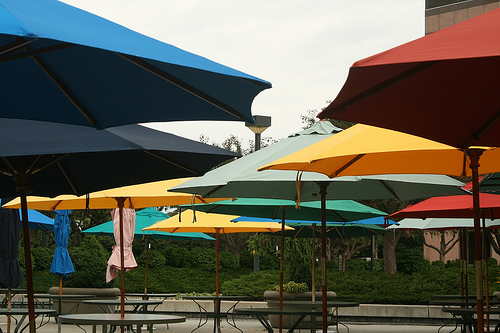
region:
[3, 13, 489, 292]
a whole lot of umbrellas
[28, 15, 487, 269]
they are all different colors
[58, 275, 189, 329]
they provide shade for the tables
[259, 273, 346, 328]
the concrete pots have bushes in them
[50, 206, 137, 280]
these umbrellas are not open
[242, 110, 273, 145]
an overhead light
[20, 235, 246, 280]
many neatly trimmed bushes line the area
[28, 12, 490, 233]
the umbrellas are blue, red, yellow, green & white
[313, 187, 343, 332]
the posts appear to be wooden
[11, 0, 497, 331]
this photo was taken on a cloudy day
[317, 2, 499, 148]
an open red umbrella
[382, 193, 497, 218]
an open red umbrella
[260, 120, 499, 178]
an open yellow umbrella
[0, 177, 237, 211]
an open yellow umbrella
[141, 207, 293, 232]
an open yellow umbrella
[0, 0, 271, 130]
an open blue umbrella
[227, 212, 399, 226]
an open blue umbrella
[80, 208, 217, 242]
an open blue umbrella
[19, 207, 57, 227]
an open blue umbrella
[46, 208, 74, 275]
an closed blue umbrella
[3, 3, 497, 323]
large patio umbrellas above tables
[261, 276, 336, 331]
cement planter on patio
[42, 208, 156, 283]
closed patio umbrellas on tables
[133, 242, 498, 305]
bushes by patio wall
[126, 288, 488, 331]
cement wall around patio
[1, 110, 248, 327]
large umbrella with wooden ribs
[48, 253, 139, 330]
cement planter with bush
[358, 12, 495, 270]
stone building by tree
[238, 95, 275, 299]
street light on pole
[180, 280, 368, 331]
round metal tables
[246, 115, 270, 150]
Black and yellow light on pole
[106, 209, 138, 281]
Closed pink umbrella on pole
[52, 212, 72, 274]
Closed blue umbrella on pole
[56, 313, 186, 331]
Round table sitting outside on patio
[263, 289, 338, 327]
Concrete planter in background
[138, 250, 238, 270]
Group of green bushes in background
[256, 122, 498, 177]
Open yellow umbrella on pole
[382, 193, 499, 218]
Open red umbrella on pole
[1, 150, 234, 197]
Metal wires holding up umbrella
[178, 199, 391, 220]
Open green umbrella on pole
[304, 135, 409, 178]
open yellow colored umbrella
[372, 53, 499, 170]
open red colored umbrella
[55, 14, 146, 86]
open blue colored umbrella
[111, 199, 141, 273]
closed off white umbrella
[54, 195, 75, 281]
closed blue umbrella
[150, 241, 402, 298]
green bushes in the distance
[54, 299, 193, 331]
table under an open yellow umbrella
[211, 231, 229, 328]
wooden pole under an umbrella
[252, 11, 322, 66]
grey overcast sky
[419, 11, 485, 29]
tan side of a building